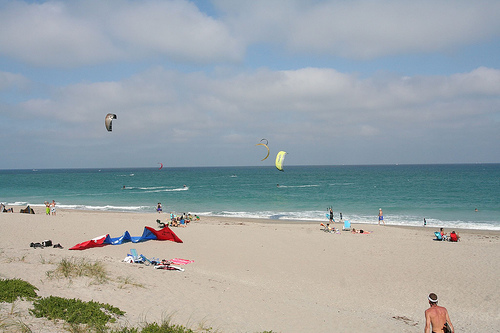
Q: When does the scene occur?
A: Daytime.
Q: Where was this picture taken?
A: At the beach.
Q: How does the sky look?
A: Mostly cloudy.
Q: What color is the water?
A: Greenish.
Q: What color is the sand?
A: White.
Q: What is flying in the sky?
A: Kites.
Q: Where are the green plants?
A: To the left.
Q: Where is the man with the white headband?
A: To the right.